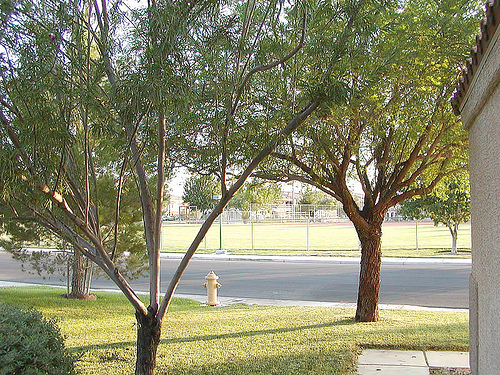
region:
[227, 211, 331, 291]
a fence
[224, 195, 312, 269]
a fence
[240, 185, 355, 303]
a fence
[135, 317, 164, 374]
A tree trunk in the photo.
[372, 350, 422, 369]
A paved path in the photo.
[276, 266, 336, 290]
A road surface with tarmac.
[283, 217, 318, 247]
A metallic fence in the picture.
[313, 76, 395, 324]
A tree in the photo.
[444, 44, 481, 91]
A brick roof in the photo.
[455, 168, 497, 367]
A concrete wall in the picture.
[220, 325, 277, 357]
A field with grass.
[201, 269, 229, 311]
A water hydrant in the picture.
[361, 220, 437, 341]
a tree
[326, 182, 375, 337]
a tree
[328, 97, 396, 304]
a tree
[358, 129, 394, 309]
a tree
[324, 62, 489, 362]
a tree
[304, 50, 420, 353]
a tree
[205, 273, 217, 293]
this is a hydrant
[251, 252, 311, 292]
this is a road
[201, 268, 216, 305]
the hydrant is metallic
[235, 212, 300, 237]
this is a fence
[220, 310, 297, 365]
this is a grass area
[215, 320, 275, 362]
the grass is green in color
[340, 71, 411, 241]
this is a tree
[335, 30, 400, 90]
the leaves are green in color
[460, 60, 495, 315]
this is a building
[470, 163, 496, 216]
this is the wall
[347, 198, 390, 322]
this is a tree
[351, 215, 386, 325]
the tree is woody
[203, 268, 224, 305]
this is a hydrant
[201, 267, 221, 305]
the hydrant is white in color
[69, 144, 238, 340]
the tree s branchy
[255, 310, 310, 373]
the grass is well treamed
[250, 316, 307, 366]
the grass is green in color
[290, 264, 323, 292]
te road is tarmacked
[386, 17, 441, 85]
the leaves are green in color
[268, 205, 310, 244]
this is a fence